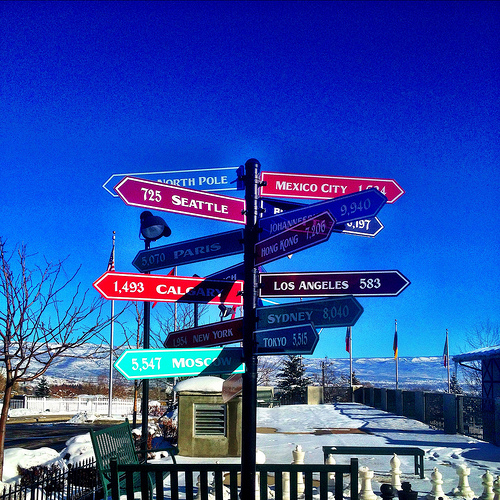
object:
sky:
[157, 21, 354, 133]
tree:
[0, 237, 138, 491]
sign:
[113, 175, 247, 224]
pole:
[240, 374, 257, 500]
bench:
[88, 417, 177, 500]